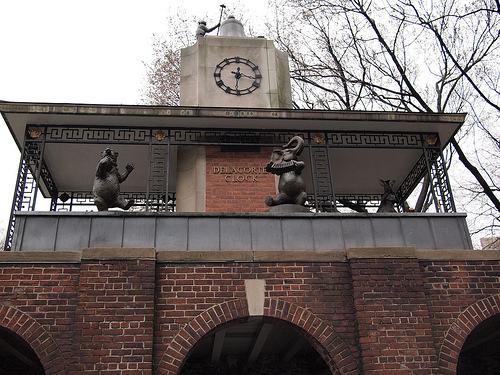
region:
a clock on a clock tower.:
[207, 56, 268, 101]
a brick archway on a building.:
[149, 276, 344, 373]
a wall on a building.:
[9, 211, 473, 253]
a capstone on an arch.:
[241, 270, 271, 322]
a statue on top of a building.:
[190, 0, 280, 38]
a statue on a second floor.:
[252, 131, 322, 219]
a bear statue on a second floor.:
[84, 144, 139, 224]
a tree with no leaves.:
[144, 2, 495, 107]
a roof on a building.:
[0, 96, 469, 198]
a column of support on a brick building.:
[60, 233, 163, 373]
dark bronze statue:
[79, 145, 143, 209]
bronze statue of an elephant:
[258, 138, 318, 205]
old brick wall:
[341, 254, 445, 373]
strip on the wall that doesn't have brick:
[236, 271, 278, 316]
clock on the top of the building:
[208, 47, 265, 97]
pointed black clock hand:
[241, 71, 258, 81]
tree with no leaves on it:
[151, 0, 498, 233]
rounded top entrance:
[169, 303, 345, 374]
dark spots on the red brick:
[43, 318, 108, 368]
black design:
[45, 122, 149, 142]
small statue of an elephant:
[260, 128, 327, 212]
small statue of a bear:
[87, 142, 144, 227]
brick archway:
[160, 260, 356, 374]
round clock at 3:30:
[184, 42, 304, 113]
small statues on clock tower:
[25, 111, 452, 245]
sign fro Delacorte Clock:
[207, 156, 277, 189]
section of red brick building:
[81, 272, 184, 374]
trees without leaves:
[294, 1, 497, 100]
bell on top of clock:
[203, 8, 279, 45]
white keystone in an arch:
[235, 276, 281, 319]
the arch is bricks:
[288, 311, 304, 333]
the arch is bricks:
[249, 293, 259, 308]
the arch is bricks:
[279, 303, 293, 318]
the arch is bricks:
[293, 315, 307, 333]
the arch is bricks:
[306, 311, 313, 334]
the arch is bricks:
[299, 320, 314, 334]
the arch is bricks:
[320, 327, 334, 359]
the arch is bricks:
[309, 325, 317, 338]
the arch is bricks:
[325, 331, 334, 343]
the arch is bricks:
[304, 325, 319, 342]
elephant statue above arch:
[243, 126, 315, 233]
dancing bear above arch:
[69, 141, 153, 251]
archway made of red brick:
[170, 263, 355, 372]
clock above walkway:
[183, 28, 308, 125]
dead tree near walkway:
[313, 18, 410, 79]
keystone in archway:
[232, 273, 277, 318]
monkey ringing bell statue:
[171, 5, 268, 54]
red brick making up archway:
[362, 280, 406, 347]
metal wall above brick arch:
[12, 199, 478, 284]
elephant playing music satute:
[249, 129, 357, 246]